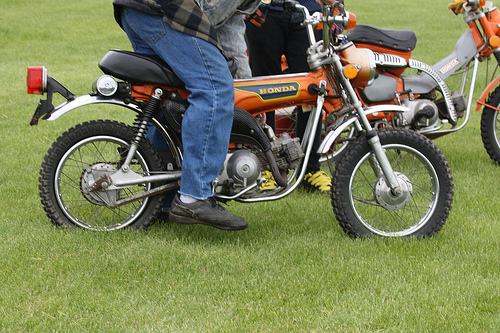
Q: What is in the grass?
A: Motorcycles.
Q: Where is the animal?
A: No animal.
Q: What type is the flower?
A: No flower.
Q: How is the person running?
A: No runner.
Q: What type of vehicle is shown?
A: Motorcycle.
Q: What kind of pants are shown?
A: Blue jeans.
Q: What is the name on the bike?
A: Honda.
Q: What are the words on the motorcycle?
A: Honda.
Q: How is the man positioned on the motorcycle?
A: Straddled on the seat.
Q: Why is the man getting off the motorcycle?
A: To talk to the other man.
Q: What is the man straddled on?
A: A motorcycle.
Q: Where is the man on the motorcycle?
A: A green field.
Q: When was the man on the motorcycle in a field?
A: Sunday afternoon.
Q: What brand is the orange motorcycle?
A: Honda.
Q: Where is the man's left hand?
A: Reaching down on the side of the motorcycle.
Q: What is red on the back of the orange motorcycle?
A: Red taillight.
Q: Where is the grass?
A: On the ground.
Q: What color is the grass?
A: Green.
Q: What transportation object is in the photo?
A: Motorcycle.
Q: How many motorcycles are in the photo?
A: Two.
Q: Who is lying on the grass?
A: No one.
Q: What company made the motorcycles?
A: Honda.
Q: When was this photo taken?
A: Daytime.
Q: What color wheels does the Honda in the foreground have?
A: Black.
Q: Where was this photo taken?
A: In a field.